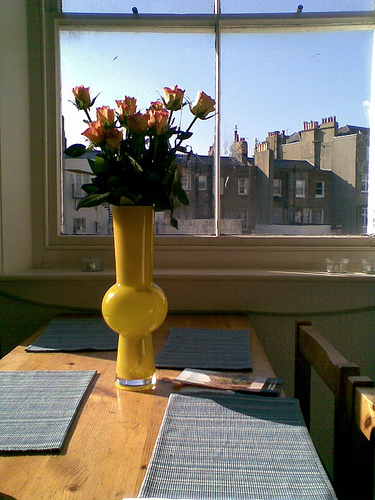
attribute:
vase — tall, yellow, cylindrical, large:
[99, 201, 167, 399]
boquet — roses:
[57, 82, 219, 207]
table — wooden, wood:
[83, 390, 146, 499]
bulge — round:
[102, 281, 167, 337]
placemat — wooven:
[145, 394, 333, 499]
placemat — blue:
[155, 321, 252, 377]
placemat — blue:
[28, 318, 107, 355]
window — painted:
[34, 1, 374, 262]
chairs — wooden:
[292, 321, 375, 446]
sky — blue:
[218, 34, 367, 115]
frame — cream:
[50, 13, 374, 30]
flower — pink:
[72, 84, 94, 112]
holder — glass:
[320, 253, 352, 273]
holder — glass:
[79, 254, 104, 272]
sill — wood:
[8, 273, 374, 287]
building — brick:
[190, 113, 371, 234]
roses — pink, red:
[65, 85, 215, 151]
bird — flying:
[111, 54, 121, 64]